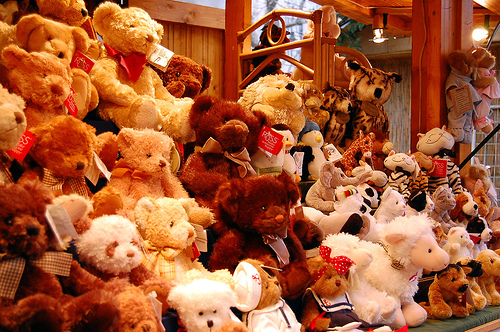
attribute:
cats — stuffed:
[384, 125, 466, 199]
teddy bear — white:
[168, 267, 239, 328]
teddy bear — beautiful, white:
[171, 277, 226, 329]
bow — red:
[310, 244, 353, 282]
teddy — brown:
[368, 76, 397, 104]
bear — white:
[329, 208, 448, 329]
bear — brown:
[231, 148, 338, 230]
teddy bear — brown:
[0, 3, 485, 329]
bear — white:
[169, 274, 246, 329]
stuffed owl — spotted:
[313, 61, 403, 146]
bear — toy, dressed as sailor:
[224, 256, 316, 327]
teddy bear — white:
[165, 275, 245, 330]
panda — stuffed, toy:
[63, 200, 154, 292]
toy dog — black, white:
[466, 213, 492, 244]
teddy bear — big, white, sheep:
[357, 217, 454, 328]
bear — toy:
[304, 250, 368, 325]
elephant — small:
[313, 161, 350, 206]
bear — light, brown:
[100, 122, 202, 200]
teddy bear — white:
[162, 276, 236, 327]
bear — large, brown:
[203, 166, 318, 294]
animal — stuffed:
[167, 270, 250, 330]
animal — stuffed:
[190, 92, 260, 207]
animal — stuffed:
[324, 203, 438, 327]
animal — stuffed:
[6, 42, 75, 124]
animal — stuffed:
[409, 121, 461, 199]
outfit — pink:
[470, 69, 493, 130]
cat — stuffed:
[380, 152, 420, 193]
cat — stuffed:
[416, 126, 467, 191]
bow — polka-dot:
[313, 237, 356, 275]